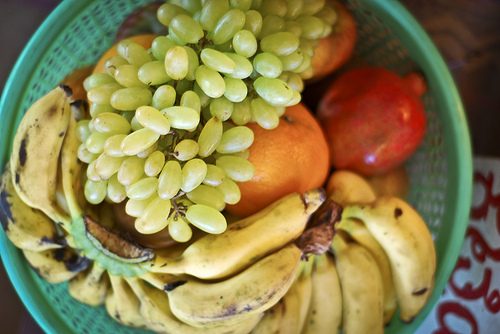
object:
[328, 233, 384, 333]
bananas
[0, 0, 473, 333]
bowl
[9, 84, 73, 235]
bananas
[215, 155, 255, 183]
grapes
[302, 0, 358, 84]
orange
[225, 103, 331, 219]
orange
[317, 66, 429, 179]
pomegranate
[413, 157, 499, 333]
paper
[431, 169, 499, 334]
lettering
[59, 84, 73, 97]
black tips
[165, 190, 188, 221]
stem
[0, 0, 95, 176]
rim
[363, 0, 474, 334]
rim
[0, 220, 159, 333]
rim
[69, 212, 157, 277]
banana stem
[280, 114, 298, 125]
stem